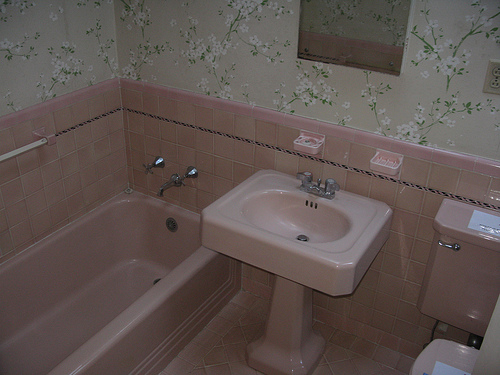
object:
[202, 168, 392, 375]
sink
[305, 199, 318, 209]
slots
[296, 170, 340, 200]
faucet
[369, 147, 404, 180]
toothbrush holder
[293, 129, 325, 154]
soap dish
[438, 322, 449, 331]
outlet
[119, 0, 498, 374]
wall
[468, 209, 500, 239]
sign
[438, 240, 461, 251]
handle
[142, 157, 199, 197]
faucet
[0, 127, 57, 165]
towel rack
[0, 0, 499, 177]
wallpaper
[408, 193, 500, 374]
toilet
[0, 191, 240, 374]
bath tub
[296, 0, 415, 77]
mirror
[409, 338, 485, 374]
lid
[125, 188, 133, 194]
plug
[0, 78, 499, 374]
tile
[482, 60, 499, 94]
electrical socket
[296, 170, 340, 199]
handles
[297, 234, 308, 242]
drain